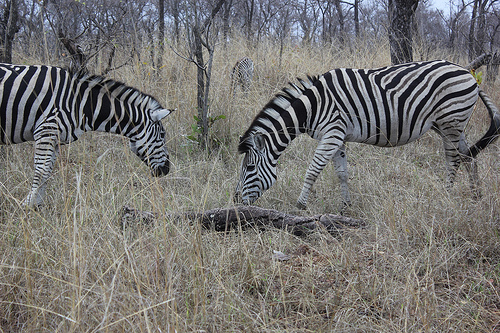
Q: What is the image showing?
A: It is showing a field.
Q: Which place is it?
A: It is a field.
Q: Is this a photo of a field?
A: Yes, it is showing a field.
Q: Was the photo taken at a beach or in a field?
A: It was taken at a field.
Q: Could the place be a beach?
A: No, it is a field.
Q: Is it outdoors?
A: Yes, it is outdoors.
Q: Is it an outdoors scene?
A: Yes, it is outdoors.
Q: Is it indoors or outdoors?
A: It is outdoors.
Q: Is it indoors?
A: No, it is outdoors.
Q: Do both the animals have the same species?
A: Yes, all the animals are zebras.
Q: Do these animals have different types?
A: No, all the animals are zebras.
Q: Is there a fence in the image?
A: No, there are no fences.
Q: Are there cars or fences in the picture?
A: No, there are no fences or cars.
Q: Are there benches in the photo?
A: No, there are no benches.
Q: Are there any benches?
A: No, there are no benches.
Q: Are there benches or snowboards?
A: No, there are no benches or snowboards.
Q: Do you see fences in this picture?
A: No, there are no fences.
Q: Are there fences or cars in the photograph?
A: No, there are no fences or cars.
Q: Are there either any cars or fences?
A: No, there are no fences or cars.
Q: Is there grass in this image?
A: Yes, there is grass.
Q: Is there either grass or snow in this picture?
A: Yes, there is grass.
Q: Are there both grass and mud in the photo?
A: No, there is grass but no mud.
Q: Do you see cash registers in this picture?
A: No, there are no cash registers.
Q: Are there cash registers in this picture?
A: No, there are no cash registers.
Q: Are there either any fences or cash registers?
A: No, there are no cash registers or fences.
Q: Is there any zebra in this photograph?
A: Yes, there is a zebra.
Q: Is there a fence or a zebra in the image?
A: Yes, there is a zebra.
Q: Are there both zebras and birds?
A: No, there is a zebra but no birds.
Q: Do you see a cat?
A: No, there are no cats.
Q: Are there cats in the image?
A: No, there are no cats.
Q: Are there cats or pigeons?
A: No, there are no cats or pigeons.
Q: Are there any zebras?
A: Yes, there is a zebra.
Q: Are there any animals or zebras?
A: Yes, there is a zebra.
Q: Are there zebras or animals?
A: Yes, there is a zebra.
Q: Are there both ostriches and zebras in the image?
A: No, there is a zebra but no ostriches.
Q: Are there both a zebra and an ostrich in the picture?
A: No, there is a zebra but no ostriches.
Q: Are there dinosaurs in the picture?
A: No, there are no dinosaurs.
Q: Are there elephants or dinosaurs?
A: No, there are no dinosaurs or elephants.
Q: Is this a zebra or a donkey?
A: This is a zebra.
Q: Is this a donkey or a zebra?
A: This is a zebra.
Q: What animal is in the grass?
A: The zebra is in the grass.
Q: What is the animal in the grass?
A: The animal is a zebra.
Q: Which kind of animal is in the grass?
A: The animal is a zebra.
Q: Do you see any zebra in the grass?
A: Yes, there is a zebra in the grass.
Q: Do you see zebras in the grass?
A: Yes, there is a zebra in the grass.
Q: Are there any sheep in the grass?
A: No, there is a zebra in the grass.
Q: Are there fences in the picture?
A: No, there are no fences.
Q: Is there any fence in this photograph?
A: No, there are no fences.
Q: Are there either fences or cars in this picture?
A: No, there are no fences or cars.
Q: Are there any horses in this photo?
A: No, there are no horses.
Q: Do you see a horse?
A: No, there are no horses.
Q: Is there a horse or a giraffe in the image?
A: No, there are no horses or giraffes.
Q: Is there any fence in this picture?
A: No, there are no fences.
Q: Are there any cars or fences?
A: No, there are no fences or cars.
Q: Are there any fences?
A: No, there are no fences.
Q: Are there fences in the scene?
A: No, there are no fences.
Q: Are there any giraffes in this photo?
A: No, there are no giraffes.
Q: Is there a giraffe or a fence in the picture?
A: No, there are no giraffes or fences.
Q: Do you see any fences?
A: No, there are no fences.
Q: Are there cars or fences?
A: No, there are no fences or cars.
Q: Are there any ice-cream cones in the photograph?
A: No, there are no ice-cream cones.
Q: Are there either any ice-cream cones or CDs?
A: No, there are no ice-cream cones or cds.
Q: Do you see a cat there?
A: No, there are no cats.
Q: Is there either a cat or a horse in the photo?
A: No, there are no cats or horses.